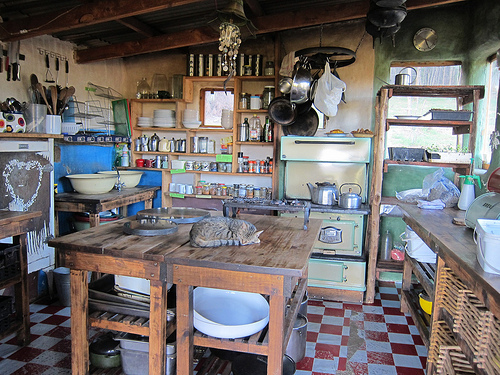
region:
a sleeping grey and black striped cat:
[188, 215, 265, 250]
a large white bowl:
[186, 285, 269, 339]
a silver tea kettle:
[302, 177, 333, 203]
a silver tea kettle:
[329, 182, 360, 208]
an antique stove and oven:
[275, 133, 370, 301]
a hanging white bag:
[314, 58, 344, 120]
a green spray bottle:
[454, 171, 482, 209]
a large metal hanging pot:
[289, 56, 312, 103]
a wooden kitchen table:
[171, 213, 321, 370]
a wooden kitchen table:
[46, 210, 203, 370]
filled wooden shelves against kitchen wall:
[130, 41, 278, 207]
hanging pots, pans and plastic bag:
[265, 26, 360, 132]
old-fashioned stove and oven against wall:
[277, 127, 367, 297]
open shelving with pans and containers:
[377, 61, 479, 266]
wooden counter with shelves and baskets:
[395, 205, 495, 370]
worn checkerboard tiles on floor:
[305, 286, 420, 366]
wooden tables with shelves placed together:
[51, 205, 316, 360]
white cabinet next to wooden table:
[1, 130, 52, 340]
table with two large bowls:
[55, 145, 160, 217]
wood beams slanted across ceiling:
[36, 7, 413, 49]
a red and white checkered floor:
[1, 280, 431, 373]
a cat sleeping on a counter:
[191, 215, 263, 245]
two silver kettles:
[305, 179, 363, 209]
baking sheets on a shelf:
[86, 273, 174, 320]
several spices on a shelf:
[238, 150, 273, 172]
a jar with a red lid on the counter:
[193, 184, 204, 196]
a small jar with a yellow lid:
[221, 185, 228, 196]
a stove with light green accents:
[279, 133, 371, 305]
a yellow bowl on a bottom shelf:
[418, 292, 433, 314]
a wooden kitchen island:
[46, 206, 323, 373]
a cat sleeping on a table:
[184, 201, 268, 261]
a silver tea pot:
[307, 174, 339, 216]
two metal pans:
[67, 167, 147, 196]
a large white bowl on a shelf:
[182, 297, 277, 342]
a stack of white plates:
[151, 104, 175, 131]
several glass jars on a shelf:
[188, 180, 275, 200]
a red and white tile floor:
[321, 315, 401, 374]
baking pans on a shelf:
[77, 282, 160, 329]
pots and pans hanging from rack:
[263, 34, 360, 144]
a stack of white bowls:
[220, 105, 235, 135]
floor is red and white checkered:
[331, 314, 418, 370]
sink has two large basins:
[87, 168, 152, 194]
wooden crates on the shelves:
[443, 282, 465, 369]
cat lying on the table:
[194, 214, 264, 252]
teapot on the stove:
[331, 179, 375, 210]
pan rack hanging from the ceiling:
[276, 0, 366, 128]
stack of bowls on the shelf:
[215, 103, 240, 141]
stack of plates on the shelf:
[155, 108, 180, 130]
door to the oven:
[321, 221, 377, 257]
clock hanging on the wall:
[419, 27, 449, 65]